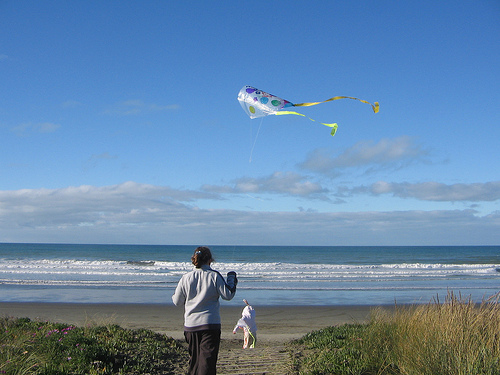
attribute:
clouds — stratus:
[3, 135, 499, 245]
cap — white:
[1, 257, 498, 282]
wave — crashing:
[1, 247, 498, 290]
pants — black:
[175, 313, 227, 373]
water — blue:
[335, 248, 491, 270]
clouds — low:
[0, 150, 497, 245]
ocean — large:
[1, 241, 498, 298]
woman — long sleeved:
[171, 245, 237, 372]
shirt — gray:
[171, 266, 236, 326]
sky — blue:
[3, 6, 484, 245]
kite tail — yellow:
[295, 91, 388, 119]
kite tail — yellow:
[263, 102, 339, 141]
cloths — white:
[238, 306, 256, 343]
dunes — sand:
[99, 306, 404, 337]